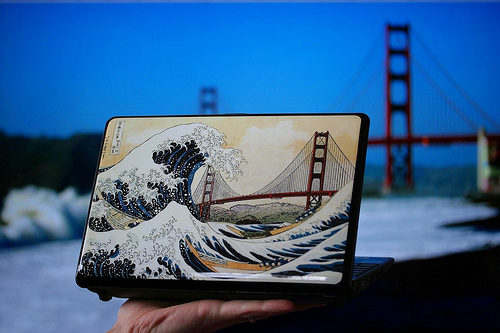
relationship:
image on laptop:
[81, 100, 371, 285] [75, 103, 413, 318]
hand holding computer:
[97, 292, 332, 332] [71, 110, 371, 302]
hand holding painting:
[97, 292, 332, 332] [79, 89, 417, 320]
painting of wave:
[79, 117, 357, 295] [110, 127, 249, 207]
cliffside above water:
[4, 134, 105, 188] [4, 186, 120, 331]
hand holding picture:
[97, 292, 332, 332] [74, 112, 371, 291]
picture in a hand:
[74, 112, 371, 291] [105, 297, 329, 331]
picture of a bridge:
[74, 112, 371, 291] [186, 130, 356, 224]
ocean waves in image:
[110, 132, 302, 275] [92, 116, 367, 294]